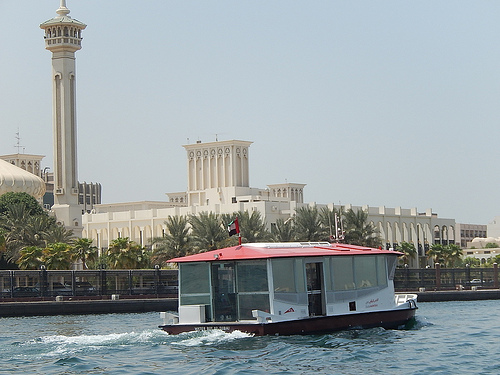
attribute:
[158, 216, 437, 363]
boat — interesting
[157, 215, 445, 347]
boat — special, unique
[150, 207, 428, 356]
boat — unique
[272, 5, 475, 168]
sky — clear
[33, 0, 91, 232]
tower — thin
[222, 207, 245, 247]
flag — blue, white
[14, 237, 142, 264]
trees — palm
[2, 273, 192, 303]
lot — parking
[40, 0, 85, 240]
tower — tall, white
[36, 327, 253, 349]
waves — white, splashed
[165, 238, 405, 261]
rooftop — red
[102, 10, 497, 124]
skies — clear, blue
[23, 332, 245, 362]
waves — white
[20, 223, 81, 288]
tree — palm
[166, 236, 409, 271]
roof — red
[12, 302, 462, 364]
water — blue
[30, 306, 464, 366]
water — blue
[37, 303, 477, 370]
water — blue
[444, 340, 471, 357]
waves — small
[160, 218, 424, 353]
boat — interesting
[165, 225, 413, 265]
roof — red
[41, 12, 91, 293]
tower — large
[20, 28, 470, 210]
sky — blue, hazy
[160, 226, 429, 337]
boat — nice, small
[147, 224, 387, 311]
boat — unique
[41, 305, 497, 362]
water — interesting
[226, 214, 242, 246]
flag — on a houseboat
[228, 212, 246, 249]
flag — red white and black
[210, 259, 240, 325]
an entrance — to the boat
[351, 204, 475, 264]
tall/white structure — with many arches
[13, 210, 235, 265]
palm trees — behind the boat